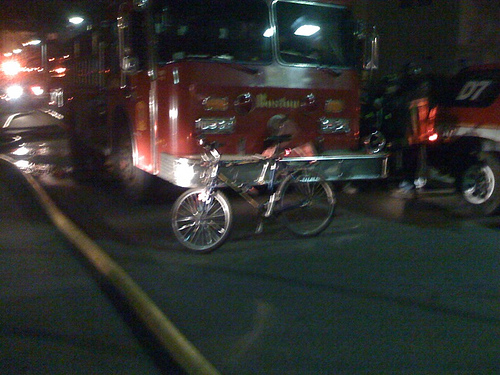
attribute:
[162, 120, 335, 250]
bicycle — silver, chrome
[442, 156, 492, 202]
tire — black